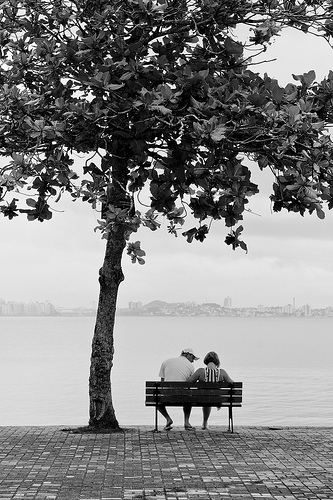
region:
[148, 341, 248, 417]
couple sitting on bench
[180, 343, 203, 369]
hat on man's head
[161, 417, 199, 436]
two feet in flip flops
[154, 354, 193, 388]
short sleeved tee shirt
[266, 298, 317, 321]
buildings on horizon beyond water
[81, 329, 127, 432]
trunk of tree overlooking water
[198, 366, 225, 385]
striped sleeveless top on woman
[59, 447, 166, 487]
bricks in water walkway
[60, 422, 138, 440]
patch of dirt below tree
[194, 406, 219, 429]
bare leg of woman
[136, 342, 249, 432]
couple sitting on a bench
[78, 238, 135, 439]
the trunk of a tree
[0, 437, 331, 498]
a cobblestone walkway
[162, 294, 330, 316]
a city beyond the water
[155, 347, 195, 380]
a man wearing a white cap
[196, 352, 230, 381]
a woman wearing a striped shirt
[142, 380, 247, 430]
a park bench by the water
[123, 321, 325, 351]
a large body of water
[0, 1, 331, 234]
a large leafy tree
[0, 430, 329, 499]
a cobblestone foot path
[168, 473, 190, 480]
small white tile on ground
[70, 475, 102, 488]
gray tile on ground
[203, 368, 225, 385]
black lines in woman's shirt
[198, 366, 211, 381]
white edge of woman's shirt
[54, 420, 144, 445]
large hole in sidewalk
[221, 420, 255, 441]
sturdy legs on black bench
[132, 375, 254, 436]
black bench on the ground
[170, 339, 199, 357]
white cap on man's head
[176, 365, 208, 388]
wrinkle in man's shirt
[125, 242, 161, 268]
large cluster of leaves on trees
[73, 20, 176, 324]
this is a tree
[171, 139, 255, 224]
the tree has green leaves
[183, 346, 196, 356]
this is cap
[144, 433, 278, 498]
this is a pavement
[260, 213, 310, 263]
this is the sky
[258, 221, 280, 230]
the sky is blue in color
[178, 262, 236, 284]
this are the clouds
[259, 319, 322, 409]
this is a water body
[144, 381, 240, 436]
this is a bench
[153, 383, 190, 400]
the bench is wooden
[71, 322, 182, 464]
Large tree near bench.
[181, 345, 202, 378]
Man wearing white hat.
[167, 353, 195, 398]
Man wearing white shirt.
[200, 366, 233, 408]
Person wearing tank top.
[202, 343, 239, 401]
Person has short hair.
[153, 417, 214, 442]
Man wearing sandals.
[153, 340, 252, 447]
2 people sitting on park bench.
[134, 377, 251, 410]
Park bench made of wood.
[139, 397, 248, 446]
Legs on park bench are dark.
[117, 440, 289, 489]
Sidewalk made of bricks.